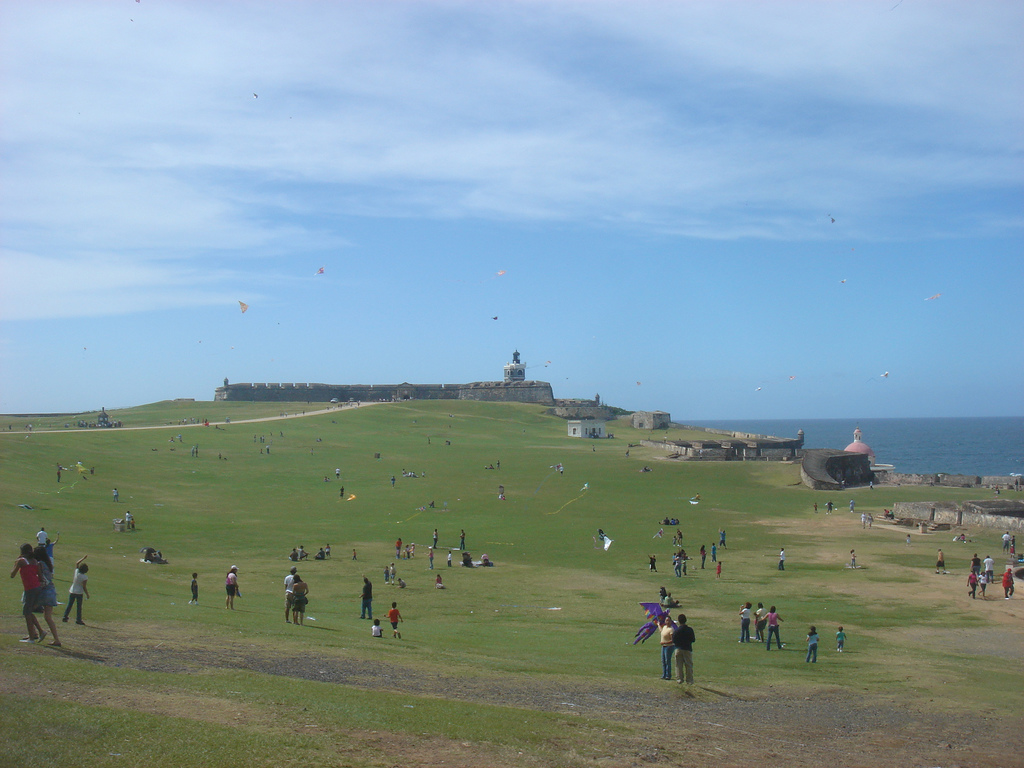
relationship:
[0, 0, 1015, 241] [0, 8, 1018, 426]
clouds in sky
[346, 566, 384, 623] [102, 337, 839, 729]
person in field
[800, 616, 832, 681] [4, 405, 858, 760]
person in field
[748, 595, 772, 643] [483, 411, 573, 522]
person in field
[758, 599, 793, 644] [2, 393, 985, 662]
person in field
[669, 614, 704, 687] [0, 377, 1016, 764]
person in field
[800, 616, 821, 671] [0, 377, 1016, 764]
person in field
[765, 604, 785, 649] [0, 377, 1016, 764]
person in field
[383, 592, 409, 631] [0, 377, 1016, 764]
person in field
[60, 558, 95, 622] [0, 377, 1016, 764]
person in field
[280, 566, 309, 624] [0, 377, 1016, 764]
person in field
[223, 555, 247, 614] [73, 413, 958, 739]
person in field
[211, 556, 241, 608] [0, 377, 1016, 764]
person in field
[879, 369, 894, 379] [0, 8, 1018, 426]
kites in sky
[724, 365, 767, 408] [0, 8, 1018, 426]
clouds in sky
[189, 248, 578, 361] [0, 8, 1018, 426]
kites in sky